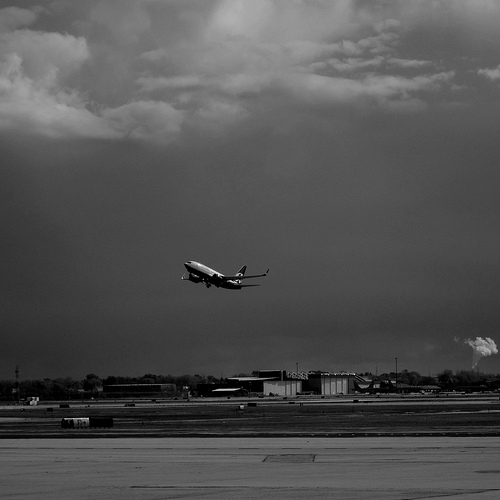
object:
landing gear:
[203, 281, 211, 289]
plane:
[179, 259, 271, 292]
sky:
[0, 0, 500, 385]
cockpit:
[185, 259, 193, 264]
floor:
[0, 436, 500, 500]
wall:
[262, 379, 302, 398]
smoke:
[465, 335, 498, 370]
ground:
[0, 392, 500, 500]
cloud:
[0, 18, 93, 94]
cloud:
[0, 0, 37, 33]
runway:
[0, 436, 500, 499]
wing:
[220, 268, 270, 282]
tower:
[13, 364, 21, 406]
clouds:
[472, 66, 500, 87]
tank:
[60, 415, 114, 430]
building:
[307, 370, 356, 396]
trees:
[77, 375, 104, 397]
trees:
[174, 376, 199, 394]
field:
[0, 391, 500, 439]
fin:
[236, 263, 246, 283]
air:
[201, 167, 330, 233]